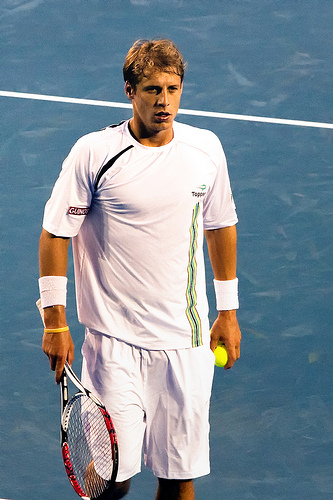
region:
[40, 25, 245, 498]
this is a person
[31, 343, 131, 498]
this is a racket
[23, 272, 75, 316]
this is a hand band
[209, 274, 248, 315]
this is a hand band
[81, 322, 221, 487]
these are white shorts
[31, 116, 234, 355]
this is a shirt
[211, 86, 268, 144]
this is a line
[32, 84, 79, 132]
this is a line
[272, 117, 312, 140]
this is a line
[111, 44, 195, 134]
a man with blonde hair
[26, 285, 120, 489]
a man holding a tennis racket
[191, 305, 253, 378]
a man holding a tennis ball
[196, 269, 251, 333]
a man wearing a white wrist band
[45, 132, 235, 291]
a man wearing a white shirt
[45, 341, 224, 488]
a man wearing white shorts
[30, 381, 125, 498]
a red,white and black tennis racket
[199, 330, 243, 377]
a yellow tennis ball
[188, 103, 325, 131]
a white line on a tennis court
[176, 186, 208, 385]
multicolored stripes on a shirt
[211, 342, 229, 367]
A tennis ball being held by a man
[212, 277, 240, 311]
A white wrist band being worn by a tennis player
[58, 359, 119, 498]
A white, black, and red tennis wracket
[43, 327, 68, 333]
A yellow bracelet being worn by a tennis player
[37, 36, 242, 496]
A man playing tennis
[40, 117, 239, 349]
A white t-shirt being worn by a tennis player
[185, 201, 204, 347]
A rainbow stripe on a white t-shirt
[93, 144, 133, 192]
A black stripe on a white t-shirt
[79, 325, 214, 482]
White shorts being worn by a tennis player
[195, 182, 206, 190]
A green logo on a white t-shirt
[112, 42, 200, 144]
head of a person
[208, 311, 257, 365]
hand of a person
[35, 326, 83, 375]
hand of a person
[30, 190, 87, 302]
arm of a person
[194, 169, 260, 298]
arm of a person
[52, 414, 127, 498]
leg of a person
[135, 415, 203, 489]
leg of a person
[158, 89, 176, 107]
nose of a person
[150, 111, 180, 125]
mouth of a person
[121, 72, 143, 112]
ear of a person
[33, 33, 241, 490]
tennis player holding racket and wearing white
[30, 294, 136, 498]
black and red tennis racket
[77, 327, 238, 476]
white shorts on tennis player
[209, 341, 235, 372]
yellow ball in hand of tennis player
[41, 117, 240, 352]
white shirt on tennis player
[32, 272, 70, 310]
white wrist band on tennis player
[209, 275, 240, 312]
white band onwrist of tennis player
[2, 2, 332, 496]
blue tennis court with white lines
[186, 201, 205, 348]
yellow, maroon, brown and green stripes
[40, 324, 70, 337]
yellow wrist band on tennis player